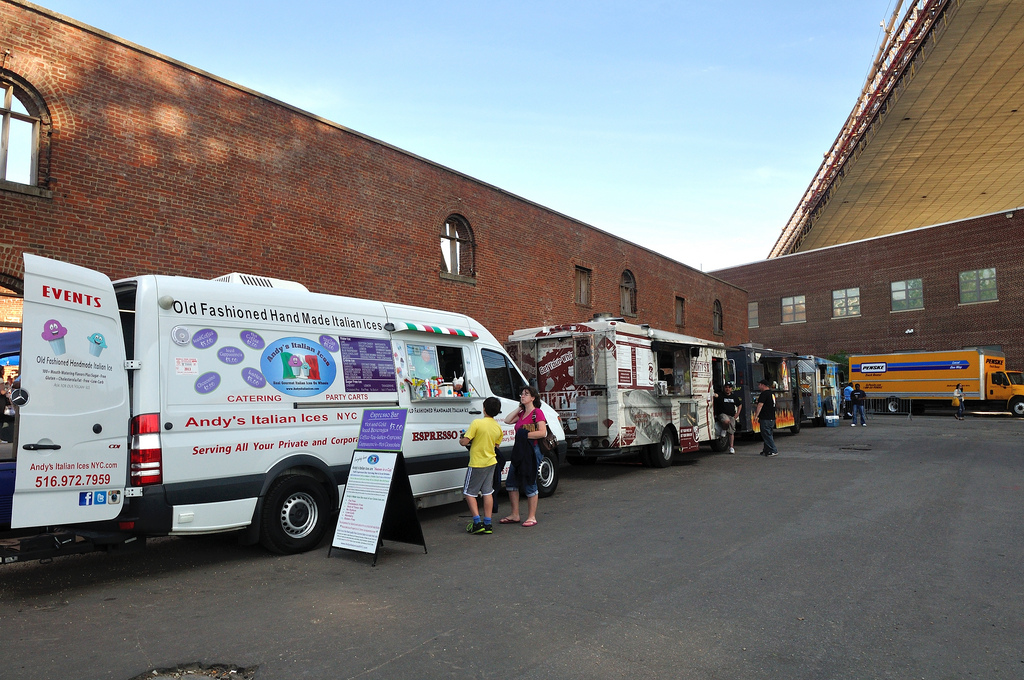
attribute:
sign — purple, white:
[324, 404, 431, 569]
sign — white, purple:
[322, 398, 439, 576]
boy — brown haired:
[751, 363, 795, 461]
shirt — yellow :
[458, 396, 515, 481]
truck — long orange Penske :
[834, 322, 992, 409]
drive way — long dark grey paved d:
[611, 476, 968, 652]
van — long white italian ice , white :
[19, 238, 590, 563]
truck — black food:
[23, 214, 587, 582]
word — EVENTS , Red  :
[13, 229, 582, 558]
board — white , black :
[337, 404, 435, 573]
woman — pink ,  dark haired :
[499, 372, 554, 520]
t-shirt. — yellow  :
[451, 409, 514, 474]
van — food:
[131, 264, 566, 554]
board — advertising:
[312, 404, 440, 575]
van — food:
[120, 247, 551, 574]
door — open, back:
[16, 247, 159, 582]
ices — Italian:
[262, 340, 355, 407]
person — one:
[703, 374, 781, 476]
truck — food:
[552, 292, 797, 468]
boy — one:
[461, 396, 511, 543]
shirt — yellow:
[457, 419, 501, 465]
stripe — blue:
[846, 342, 974, 375]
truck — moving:
[841, 335, 1010, 418]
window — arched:
[424, 203, 496, 281]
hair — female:
[517, 387, 541, 413]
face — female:
[517, 387, 539, 414]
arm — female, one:
[528, 415, 550, 459]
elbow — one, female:
[534, 420, 561, 453]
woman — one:
[513, 415, 546, 476]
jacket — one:
[513, 424, 546, 479]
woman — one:
[500, 435, 561, 515]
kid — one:
[450, 379, 505, 518]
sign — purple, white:
[326, 388, 441, 566]